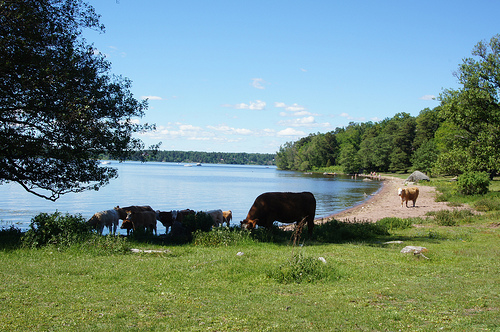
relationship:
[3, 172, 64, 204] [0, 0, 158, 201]
branch on tree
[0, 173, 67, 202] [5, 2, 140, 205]
branch on tree